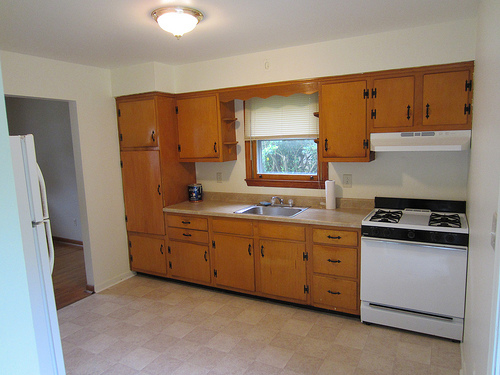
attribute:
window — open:
[251, 97, 319, 173]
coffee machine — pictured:
[182, 178, 204, 206]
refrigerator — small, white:
[14, 130, 73, 373]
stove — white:
[354, 189, 474, 337]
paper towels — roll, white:
[318, 178, 343, 212]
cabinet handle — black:
[147, 128, 157, 146]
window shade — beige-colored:
[243, 101, 320, 142]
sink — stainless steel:
[239, 205, 303, 220]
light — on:
[156, 10, 198, 39]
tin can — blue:
[184, 180, 205, 203]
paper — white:
[323, 177, 339, 209]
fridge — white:
[2, 133, 70, 373]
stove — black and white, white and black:
[360, 191, 470, 341]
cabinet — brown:
[369, 60, 475, 134]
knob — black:
[322, 229, 347, 239]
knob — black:
[323, 253, 342, 263]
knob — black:
[320, 283, 344, 297]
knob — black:
[179, 216, 197, 221]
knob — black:
[178, 230, 195, 237]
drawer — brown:
[312, 229, 358, 246]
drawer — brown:
[312, 242, 361, 280]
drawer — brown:
[162, 210, 212, 230]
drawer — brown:
[159, 224, 211, 242]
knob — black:
[323, 230, 343, 240]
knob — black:
[324, 251, 343, 261]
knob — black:
[322, 286, 342, 295]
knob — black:
[178, 216, 194, 224]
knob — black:
[176, 227, 192, 235]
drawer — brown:
[308, 223, 360, 247]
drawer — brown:
[306, 243, 359, 281]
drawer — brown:
[308, 270, 360, 313]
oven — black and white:
[358, 221, 469, 321]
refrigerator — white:
[6, 130, 66, 372]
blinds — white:
[243, 92, 319, 142]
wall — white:
[0, 9, 496, 370]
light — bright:
[146, 3, 207, 41]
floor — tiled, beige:
[55, 272, 464, 372]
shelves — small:
[219, 93, 238, 157]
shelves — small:
[313, 93, 322, 147]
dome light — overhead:
[144, 4, 209, 42]